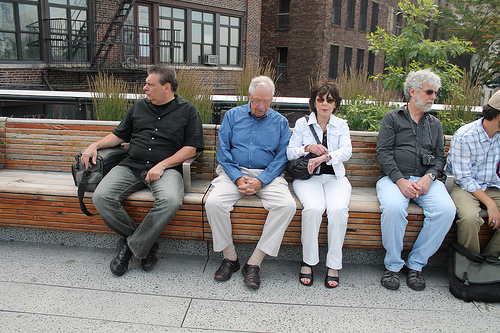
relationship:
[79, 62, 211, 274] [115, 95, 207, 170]
man in shirt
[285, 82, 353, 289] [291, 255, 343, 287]
woman on sandals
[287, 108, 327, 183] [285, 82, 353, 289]
purse on woman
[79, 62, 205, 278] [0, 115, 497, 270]
man on bench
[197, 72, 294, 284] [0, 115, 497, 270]
man on bench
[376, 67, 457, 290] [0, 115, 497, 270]
man on bench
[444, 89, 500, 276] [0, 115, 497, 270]
man on bench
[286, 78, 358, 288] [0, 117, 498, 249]
woman on bench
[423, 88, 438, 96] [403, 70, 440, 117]
glasses on a man's head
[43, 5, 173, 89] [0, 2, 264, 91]
starway on a building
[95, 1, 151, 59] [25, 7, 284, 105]
brick wall on a building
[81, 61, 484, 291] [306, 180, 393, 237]
five people sitting on a bench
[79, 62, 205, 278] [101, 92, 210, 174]
man wearing shirt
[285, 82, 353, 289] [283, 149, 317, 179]
woman holding purse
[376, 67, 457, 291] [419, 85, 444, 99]
man wearing glasses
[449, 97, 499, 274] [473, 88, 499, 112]
man wearing cap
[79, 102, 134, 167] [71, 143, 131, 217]
arm on a duffel bag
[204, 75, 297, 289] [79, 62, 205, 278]
man wearing man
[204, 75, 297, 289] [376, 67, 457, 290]
man wearing man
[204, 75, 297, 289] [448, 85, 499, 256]
man wearing man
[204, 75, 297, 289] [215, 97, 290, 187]
man wearing shirt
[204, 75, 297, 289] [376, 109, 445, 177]
man wearing shirt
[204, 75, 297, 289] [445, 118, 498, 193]
man wearing shirt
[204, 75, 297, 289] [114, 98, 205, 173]
man wearing shirt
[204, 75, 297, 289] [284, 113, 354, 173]
man wearing shirt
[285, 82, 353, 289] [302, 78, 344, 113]
woman with brown hair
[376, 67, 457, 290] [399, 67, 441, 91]
man with hair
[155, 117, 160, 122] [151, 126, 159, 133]
buttons on buttons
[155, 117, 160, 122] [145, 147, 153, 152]
buttons on buttons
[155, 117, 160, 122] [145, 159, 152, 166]
buttons on buttons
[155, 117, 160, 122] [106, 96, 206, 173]
buttons on shirt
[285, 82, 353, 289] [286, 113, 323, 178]
woman has a purse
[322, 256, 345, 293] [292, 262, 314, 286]
sandal wearing sandal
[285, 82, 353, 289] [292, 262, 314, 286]
woman wearing sandal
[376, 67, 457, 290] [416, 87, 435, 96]
man wearing sunglasses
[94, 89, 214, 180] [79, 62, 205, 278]
shirt sitting on man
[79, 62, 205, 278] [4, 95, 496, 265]
man sitting on bench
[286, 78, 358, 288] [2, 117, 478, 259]
woman sitting on bench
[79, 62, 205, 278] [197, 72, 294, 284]
man wearing man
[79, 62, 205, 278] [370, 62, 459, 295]
man wearing man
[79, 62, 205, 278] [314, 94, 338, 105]
man wearing sunglasses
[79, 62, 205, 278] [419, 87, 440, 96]
man wearing glasses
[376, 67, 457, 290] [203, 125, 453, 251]
man sitting on bench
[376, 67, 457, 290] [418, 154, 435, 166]
man wearing camera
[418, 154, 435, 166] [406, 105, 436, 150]
camera on strap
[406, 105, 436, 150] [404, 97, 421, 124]
strap around neck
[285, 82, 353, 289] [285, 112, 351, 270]
woman dressed in white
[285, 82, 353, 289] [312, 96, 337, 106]
woman wearing sunglasses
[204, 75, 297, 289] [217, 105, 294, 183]
man wearing shirt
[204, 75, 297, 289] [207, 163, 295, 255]
man wearing pants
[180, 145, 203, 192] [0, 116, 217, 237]
arm rest of bench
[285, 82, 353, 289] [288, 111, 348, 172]
woman wearing blouse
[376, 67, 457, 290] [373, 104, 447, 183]
man wearing shirt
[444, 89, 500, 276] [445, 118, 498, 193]
man wearing shirt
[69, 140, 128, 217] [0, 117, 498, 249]
duffel bag on bench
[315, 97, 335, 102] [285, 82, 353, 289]
sunglasses on woman